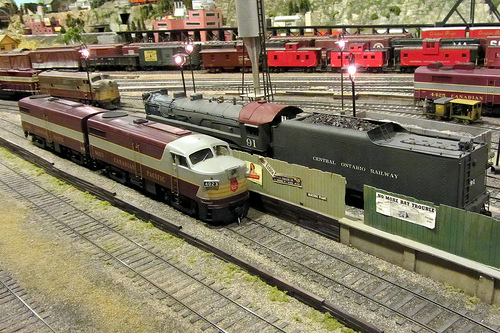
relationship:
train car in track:
[268, 111, 493, 215] [104, 93, 496, 229]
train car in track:
[145, 82, 493, 215] [104, 93, 496, 229]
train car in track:
[268, 111, 493, 215] [115, 60, 417, 98]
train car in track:
[268, 111, 493, 215] [115, 65, 419, 103]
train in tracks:
[4, 104, 493, 330] [18, 90, 254, 226]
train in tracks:
[18, 93, 252, 226] [105, 93, 498, 221]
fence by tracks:
[221, 142, 496, 262] [3, 111, 498, 330]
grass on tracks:
[9, 144, 354, 330] [0, 160, 303, 333]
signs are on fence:
[251, 158, 331, 207] [221, 141, 349, 220]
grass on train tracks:
[0, 186, 206, 333] [0, 150, 308, 330]